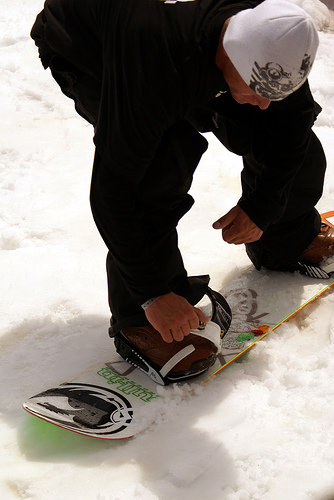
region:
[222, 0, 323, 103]
The beanie of the snowboarder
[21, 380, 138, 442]
The circular sticker on the end of the board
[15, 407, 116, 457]
The green reflection on the snow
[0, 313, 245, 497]
The snowboarder's shadow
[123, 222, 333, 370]
The snowboarder's brown boots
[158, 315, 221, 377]
The white straps on the bindings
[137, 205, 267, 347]
The snowboarder's hands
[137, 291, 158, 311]
The white bracelet on snowboarder's right wrist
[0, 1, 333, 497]
Snow covering the ground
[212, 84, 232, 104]
Zipper on the snowboarder's jacket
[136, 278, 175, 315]
the bracelet is gray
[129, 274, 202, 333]
the man is wearing a bracelet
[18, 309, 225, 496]
the shadow is on the ground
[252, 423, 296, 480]
the snow is white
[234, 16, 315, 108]
the cap is white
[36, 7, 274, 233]
the man is wearing jacket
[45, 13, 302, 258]
the man is wearing pants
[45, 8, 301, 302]
the jacket is black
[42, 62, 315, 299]
the pants is black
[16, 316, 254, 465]
the snow board is printed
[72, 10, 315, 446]
snowboarder adjusting strap around foot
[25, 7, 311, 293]
snowboarder deeply bending over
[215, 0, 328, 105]
knit hat with black graphics in front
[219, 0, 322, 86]
hat seams radiating outward from center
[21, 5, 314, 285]
snowboarder wearing black outfit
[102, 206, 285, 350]
snowboarder with bare hands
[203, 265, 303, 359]
light snow on top of board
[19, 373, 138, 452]
swirl and arrow around black and grey image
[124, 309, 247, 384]
thin and thick white straps above shoe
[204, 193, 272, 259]
thumb straight next to closed hand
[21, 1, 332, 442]
a man on a snowboard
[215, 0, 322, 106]
man wears a white beanie hat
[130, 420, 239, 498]
shadow of a mans head in the snow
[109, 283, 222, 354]
man is adjusting a buckle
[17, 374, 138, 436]
black and white design on a snowboard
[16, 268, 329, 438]
orange edge on a snowboard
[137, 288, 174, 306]
band around right wrist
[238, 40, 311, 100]
black and white design on beanie hat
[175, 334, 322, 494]
tracks and holes in the snow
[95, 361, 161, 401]
green design on snowboard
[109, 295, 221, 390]
brown shoes on the snowboard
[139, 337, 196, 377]
white straps on the snowboard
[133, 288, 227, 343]
man's hand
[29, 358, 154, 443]
design on the snowboard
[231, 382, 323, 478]
white snow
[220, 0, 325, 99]
white hat on the man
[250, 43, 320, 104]
design on the white hat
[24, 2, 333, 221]
man is wearing a black jacket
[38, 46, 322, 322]
man wearing black pants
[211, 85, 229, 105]
silver zipper